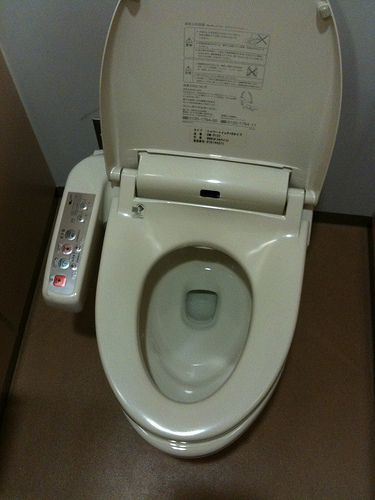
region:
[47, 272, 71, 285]
Red and black button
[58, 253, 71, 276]
Green and black button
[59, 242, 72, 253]
Red and black button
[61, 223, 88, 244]
Small grey and black button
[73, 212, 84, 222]
Small grey and black button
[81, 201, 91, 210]
Small grey and black button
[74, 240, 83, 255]
Small grey and black button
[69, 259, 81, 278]
Small grey and black button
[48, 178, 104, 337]
Small buttons on grey pannel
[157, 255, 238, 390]
Water in a pottu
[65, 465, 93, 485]
This is a bathroom floor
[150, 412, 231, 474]
This is a toilet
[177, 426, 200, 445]
This is a seat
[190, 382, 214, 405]
The bowl is empty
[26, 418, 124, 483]
The ground is brown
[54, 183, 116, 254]
These are push buttons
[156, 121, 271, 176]
This is a lid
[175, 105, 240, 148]
These are instructions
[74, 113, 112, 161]
This is an outlet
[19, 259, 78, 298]
The button is red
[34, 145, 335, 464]
an electric toilet seat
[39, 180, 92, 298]
buttons to operate the toilet seat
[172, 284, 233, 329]
drain i bottom of toilet bowl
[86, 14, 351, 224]
open lid of toilet seat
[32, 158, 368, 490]
a brown floor under toilet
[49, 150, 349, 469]
a white toilet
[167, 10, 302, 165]
instructions on the toilet seat lid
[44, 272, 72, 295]
a red square button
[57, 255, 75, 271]
a green round button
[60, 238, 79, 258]
a pink round button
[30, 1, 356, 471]
a toilet color beige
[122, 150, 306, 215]
long hinge of toilet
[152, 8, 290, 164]
a label on lid of toilet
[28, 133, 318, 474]
a control on side of toilet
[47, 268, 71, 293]
a red button on control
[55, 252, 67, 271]
a blue button on control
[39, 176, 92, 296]
buttons over silver support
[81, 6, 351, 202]
lid of toilet is up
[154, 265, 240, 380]
water of toilet is clear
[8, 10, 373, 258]
the wall back of toilet is white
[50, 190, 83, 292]
buttons on the toliet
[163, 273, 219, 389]
clear water in the toliet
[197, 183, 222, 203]
hole on the toliet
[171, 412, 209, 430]
part of the seat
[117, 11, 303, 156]
lid of the toliet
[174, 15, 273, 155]
instructions on the lid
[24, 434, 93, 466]
brown floor the toliet is sitting on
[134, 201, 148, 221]
sticker on the seat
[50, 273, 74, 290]
red button on the controls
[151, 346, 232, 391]
white toliet bowl